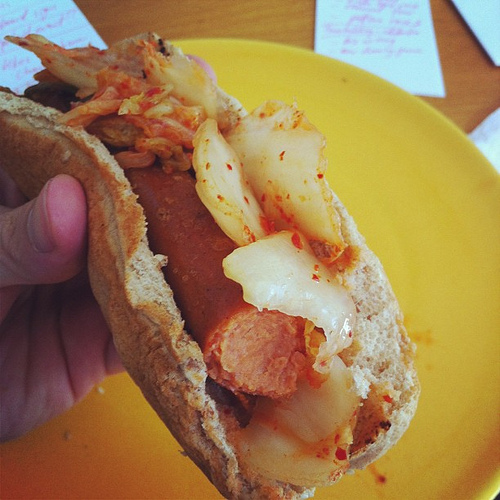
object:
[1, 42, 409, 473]
hot dog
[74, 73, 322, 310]
sauce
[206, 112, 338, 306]
vegetables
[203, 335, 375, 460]
eaten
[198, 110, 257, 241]
cucumber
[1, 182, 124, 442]
hand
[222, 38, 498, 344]
dish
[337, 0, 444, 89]
paper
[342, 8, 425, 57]
writing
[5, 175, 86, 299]
thumb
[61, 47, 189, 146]
spices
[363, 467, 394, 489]
spot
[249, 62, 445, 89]
edge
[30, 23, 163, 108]
cheese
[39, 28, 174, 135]
ketchup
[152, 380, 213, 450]
piece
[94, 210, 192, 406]
bread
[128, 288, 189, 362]
edge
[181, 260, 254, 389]
outer edge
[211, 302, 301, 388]
sausage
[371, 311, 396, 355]
holes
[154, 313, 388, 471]
bun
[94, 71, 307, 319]
top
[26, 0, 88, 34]
paper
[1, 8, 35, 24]
writing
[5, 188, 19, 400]
side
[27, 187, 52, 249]
nail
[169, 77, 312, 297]
onion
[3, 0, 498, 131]
table